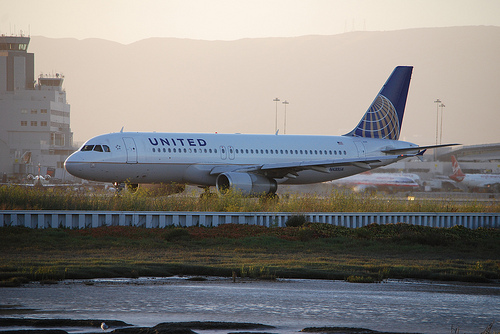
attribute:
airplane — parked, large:
[83, 125, 408, 187]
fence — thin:
[99, 206, 157, 234]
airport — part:
[458, 142, 487, 167]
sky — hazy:
[181, 19, 200, 25]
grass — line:
[114, 196, 155, 211]